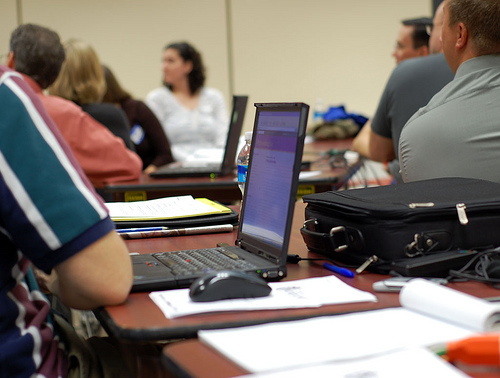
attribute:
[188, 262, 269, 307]
mouse — black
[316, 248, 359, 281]
pen — blue, ink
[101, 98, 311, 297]
computer — laptop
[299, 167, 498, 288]
bag — black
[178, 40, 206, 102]
hair — brown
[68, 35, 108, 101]
hair — blonde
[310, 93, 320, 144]
bottle — plastic, water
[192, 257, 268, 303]
mouse — black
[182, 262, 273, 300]
mouse — black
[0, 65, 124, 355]
shirt — striped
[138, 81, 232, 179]
shirt — white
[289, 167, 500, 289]
travel case — black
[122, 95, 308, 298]
laptop — on, black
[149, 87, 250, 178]
shirt — white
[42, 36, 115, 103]
hair — short, blonde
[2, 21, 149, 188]
man — gray haired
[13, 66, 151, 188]
shirt — red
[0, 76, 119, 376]
shirt — striped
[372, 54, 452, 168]
shirt — gray, tight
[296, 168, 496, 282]
briefcase — black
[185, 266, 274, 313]
mouse — black, gray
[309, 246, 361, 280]
marker — blue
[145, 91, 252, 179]
laptop — black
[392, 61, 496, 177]
shirt — grey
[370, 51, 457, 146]
shirt — grey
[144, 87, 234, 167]
shirt — white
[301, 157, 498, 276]
case — black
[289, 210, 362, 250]
handle — black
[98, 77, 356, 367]
laptop — black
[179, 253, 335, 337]
mouse — black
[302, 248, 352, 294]
pen — blue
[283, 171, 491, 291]
bag — black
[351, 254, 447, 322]
phone — silver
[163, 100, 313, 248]
laptop — on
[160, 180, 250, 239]
paper — yellow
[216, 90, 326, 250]
screen — on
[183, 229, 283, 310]
mouse — wireless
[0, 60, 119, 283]
shirt — white, striped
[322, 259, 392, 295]
pen — blue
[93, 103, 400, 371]
desks — grouped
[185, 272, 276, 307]
computer mouse — black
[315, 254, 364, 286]
pen — blue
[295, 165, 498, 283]
laptop case — black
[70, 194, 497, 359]
desk — wooden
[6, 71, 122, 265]
shirt sleeve — striped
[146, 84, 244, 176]
shirt — white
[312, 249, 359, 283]
ink pen — blue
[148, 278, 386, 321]
paper — white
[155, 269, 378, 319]
paper — white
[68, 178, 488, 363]
desk — wooden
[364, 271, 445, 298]
cell phone — silver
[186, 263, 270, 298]
mouse — black, wireless